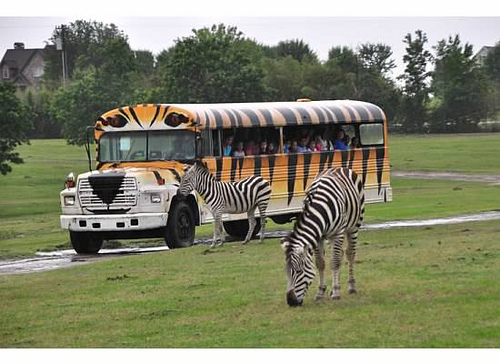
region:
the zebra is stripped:
[256, 213, 334, 297]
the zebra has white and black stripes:
[201, 182, 279, 224]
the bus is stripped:
[261, 104, 337, 119]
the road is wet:
[419, 208, 492, 225]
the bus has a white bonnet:
[50, 147, 167, 243]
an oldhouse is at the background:
[9, 50, 38, 80]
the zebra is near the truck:
[164, 156, 277, 252]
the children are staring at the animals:
[234, 122, 277, 162]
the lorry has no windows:
[223, 126, 383, 151]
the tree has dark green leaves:
[153, 45, 283, 98]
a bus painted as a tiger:
[61, 103, 389, 248]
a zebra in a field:
[178, 158, 271, 243]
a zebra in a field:
[285, 165, 365, 306]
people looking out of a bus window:
[211, 125, 277, 152]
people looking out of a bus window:
[281, 125, 354, 148]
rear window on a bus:
[357, 121, 384, 146]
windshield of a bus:
[98, 129, 193, 158]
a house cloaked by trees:
[1, 40, 52, 93]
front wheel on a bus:
[165, 203, 193, 248]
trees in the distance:
[401, 30, 489, 131]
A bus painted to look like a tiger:
[80, 92, 415, 250]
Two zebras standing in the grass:
[182, 149, 369, 302]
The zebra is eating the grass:
[270, 233, 347, 313]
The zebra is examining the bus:
[165, 160, 277, 248]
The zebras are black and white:
[187, 150, 378, 296]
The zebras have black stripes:
[178, 157, 392, 304]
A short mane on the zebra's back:
[290, 193, 319, 250]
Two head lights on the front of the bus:
[64, 192, 164, 204]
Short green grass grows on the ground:
[78, 269, 243, 343]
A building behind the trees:
[5, 43, 110, 95]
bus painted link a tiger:
[50, 100, 400, 226]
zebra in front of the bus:
[178, 166, 279, 248]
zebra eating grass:
[281, 158, 379, 319]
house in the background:
[7, 36, 84, 139]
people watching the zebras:
[207, 120, 373, 154]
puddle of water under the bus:
[32, 232, 167, 255]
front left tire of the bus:
[157, 187, 202, 248]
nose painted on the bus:
[84, 165, 134, 200]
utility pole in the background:
[56, 25, 73, 105]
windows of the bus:
[93, 129, 204, 161]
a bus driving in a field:
[33, 28, 498, 358]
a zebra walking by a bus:
[43, 40, 458, 332]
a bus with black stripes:
[27, 40, 444, 302]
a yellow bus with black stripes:
[42, 38, 453, 330]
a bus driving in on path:
[51, 59, 485, 355]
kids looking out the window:
[100, 23, 497, 223]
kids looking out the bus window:
[57, 59, 429, 298]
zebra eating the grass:
[252, 143, 497, 350]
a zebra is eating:
[235, 163, 447, 362]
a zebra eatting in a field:
[236, 106, 421, 354]